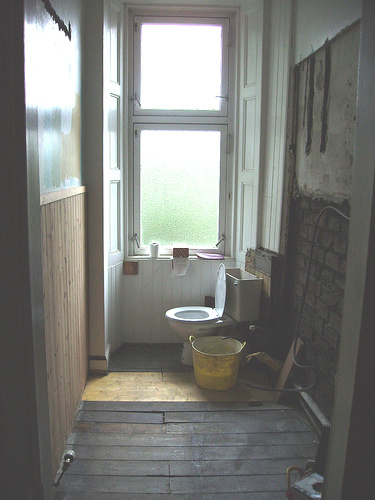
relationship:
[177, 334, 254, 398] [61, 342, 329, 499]
bucket on floor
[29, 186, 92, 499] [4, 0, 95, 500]
wood on wall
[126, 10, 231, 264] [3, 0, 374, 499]
window in bathroom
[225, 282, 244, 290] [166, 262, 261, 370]
flusher on toilet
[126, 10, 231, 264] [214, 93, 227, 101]
window has knob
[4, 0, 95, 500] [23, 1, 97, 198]
wall has top part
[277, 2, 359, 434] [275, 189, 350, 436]
wall has brick area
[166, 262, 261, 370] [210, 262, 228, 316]
toilet has lid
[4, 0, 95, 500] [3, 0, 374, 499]
wall in bathroom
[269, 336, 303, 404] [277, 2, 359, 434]
piece of wood leaning against wall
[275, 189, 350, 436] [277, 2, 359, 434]
brick area halfway up wall